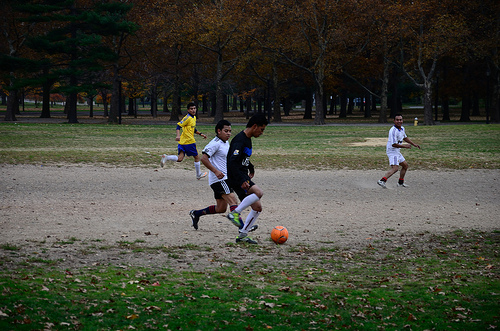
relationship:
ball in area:
[269, 224, 296, 247] [0, 101, 500, 331]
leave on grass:
[228, 250, 279, 302] [241, 293, 305, 329]